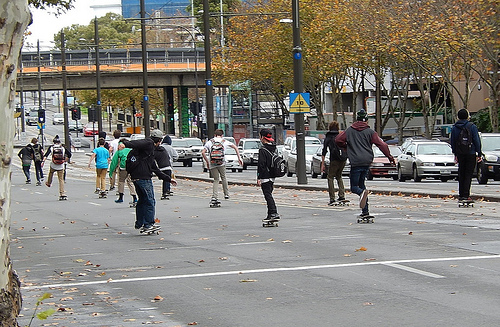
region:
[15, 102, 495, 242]
group of people skateboarding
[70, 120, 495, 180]
cars driving the same direction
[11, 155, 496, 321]
leafs scattered on the street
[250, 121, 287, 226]
young skateboarder with a backpack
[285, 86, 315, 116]
yellow and blue street sign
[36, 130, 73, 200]
skateboarder with one foot in the air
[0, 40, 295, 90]
an old overpass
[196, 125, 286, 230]
two people with backpacks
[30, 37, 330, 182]
tall metal poles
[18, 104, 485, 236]
skateboarders in the street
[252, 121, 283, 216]
this is a boy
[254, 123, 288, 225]
the boy is skating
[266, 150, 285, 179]
he is carrying a bag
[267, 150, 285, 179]
the bag is black in color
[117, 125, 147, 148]
the hand is behind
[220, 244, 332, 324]
this is the road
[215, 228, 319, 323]
the road is tarmacked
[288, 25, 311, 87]
this is a pole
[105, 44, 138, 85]
this is a bridge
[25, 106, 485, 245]
skateboarders skating down the street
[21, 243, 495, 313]
white lines painted on the street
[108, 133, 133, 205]
skateboarder wearing green shirt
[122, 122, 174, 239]
skateboader with gray hat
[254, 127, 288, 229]
skateboarder with black and orange hat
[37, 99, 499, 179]
cars driving up the street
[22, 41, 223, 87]
bridge over the roadway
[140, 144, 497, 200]
divider between south and north bound lanes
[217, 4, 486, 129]
trees lining roadway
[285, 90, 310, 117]
blue, yellow, and black street sign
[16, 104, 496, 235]
A big group of skate boarders.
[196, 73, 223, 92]
A blue light on a pole.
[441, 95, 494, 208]
A lone skate boarder.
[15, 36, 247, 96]
A bridge in the back ground.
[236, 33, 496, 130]
A bunch of yellow trees.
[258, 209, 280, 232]
A skate board with a skate boarder on it.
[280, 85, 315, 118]
A yellow and blue sign on a pole light.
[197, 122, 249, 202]
A skate boarder with a multi colored backpack.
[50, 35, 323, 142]
A group of light poles.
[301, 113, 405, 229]
Two skate boarders skating.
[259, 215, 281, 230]
skateboard on street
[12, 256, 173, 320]
section of leaves stuck to street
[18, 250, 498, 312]
white lines drawn on street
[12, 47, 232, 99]
overhead bridge over street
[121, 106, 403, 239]
three people skateboarding side by side in a line down the street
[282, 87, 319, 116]
blue and yellow traffic sign on metal pole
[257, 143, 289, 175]
black and white backpack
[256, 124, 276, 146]
black and red baseball cap worn backwards on skateboarder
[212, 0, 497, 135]
line of trees bordering street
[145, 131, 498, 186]
vehicles driving down street